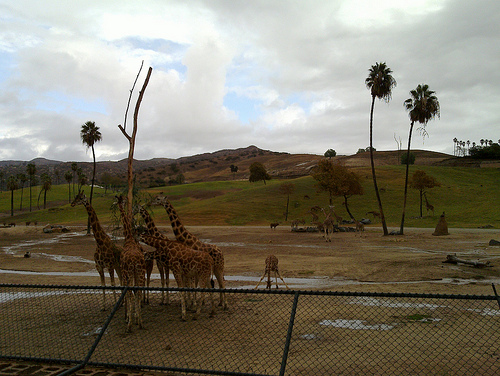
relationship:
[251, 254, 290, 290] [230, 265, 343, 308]
unbalanced-baby giraffe drinking water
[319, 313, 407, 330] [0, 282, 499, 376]
water puddle behind a chainlink fence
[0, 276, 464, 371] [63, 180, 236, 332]
chainlink fence thats leaning hard for giraffe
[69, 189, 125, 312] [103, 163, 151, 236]
giraffe standing around feeder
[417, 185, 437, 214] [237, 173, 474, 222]
adult giraffe off in distance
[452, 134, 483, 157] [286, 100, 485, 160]
palm trees way off in distance distance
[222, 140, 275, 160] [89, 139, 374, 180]
small mountain off in distance distance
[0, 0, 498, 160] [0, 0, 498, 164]
clouds in sky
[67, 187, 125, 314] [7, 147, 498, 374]
giraffe in enclosure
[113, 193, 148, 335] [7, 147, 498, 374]
giraffe in enclosure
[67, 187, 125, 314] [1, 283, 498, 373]
giraffe in zoo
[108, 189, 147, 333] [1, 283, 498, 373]
giraffe in zoo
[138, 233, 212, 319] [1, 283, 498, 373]
giraffe in zoo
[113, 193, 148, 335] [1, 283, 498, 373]
giraffe in zoo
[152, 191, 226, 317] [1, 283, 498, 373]
giraffe in zoo